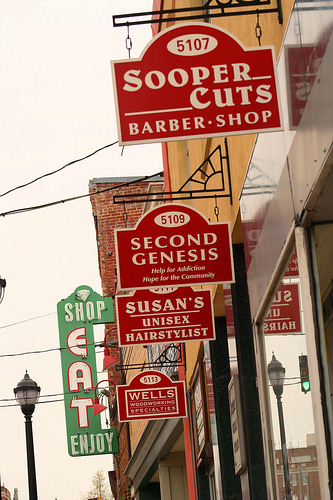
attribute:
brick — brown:
[99, 212, 114, 218]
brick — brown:
[97, 218, 109, 224]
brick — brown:
[105, 193, 115, 197]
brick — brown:
[101, 269, 115, 274]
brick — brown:
[99, 239, 108, 244]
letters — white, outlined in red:
[66, 324, 95, 428]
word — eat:
[47, 321, 108, 431]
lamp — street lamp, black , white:
[13, 370, 45, 498]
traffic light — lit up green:
[290, 333, 322, 406]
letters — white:
[125, 229, 227, 271]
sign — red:
[90, 191, 238, 289]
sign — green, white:
[55, 284, 121, 458]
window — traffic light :
[255, 240, 323, 499]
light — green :
[302, 381, 309, 389]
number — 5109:
[149, 25, 227, 59]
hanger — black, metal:
[108, 135, 233, 208]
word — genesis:
[132, 248, 218, 268]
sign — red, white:
[110, 21, 284, 145]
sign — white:
[50, 19, 306, 494]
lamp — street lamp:
[239, 324, 316, 496]